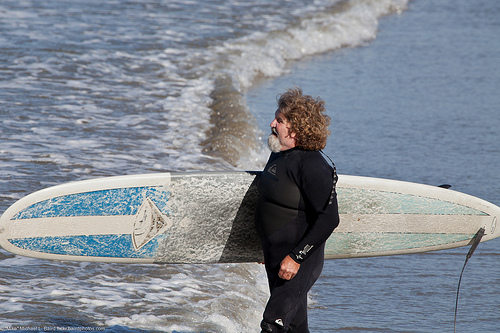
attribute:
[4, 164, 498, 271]
surf board — white, wide, long, blue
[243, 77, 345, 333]
man — white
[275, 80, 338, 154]
curly hair — bushy ginger, brown, thick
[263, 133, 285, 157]
beard — white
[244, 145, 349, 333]
wetsuit — black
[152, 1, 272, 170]
wave — small, brownish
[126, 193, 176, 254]
emblem — chevron, triangular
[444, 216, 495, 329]
tether — black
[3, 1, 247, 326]
ocean — rough, blue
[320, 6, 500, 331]
beach — brown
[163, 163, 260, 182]
edge — silver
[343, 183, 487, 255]
tail — faded, turquoise